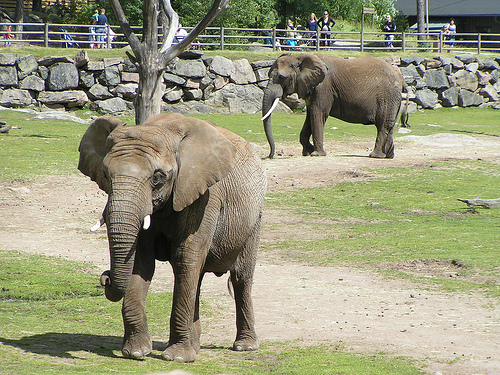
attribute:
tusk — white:
[259, 94, 281, 122]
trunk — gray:
[101, 224, 139, 302]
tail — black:
[402, 86, 413, 130]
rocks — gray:
[2, 47, 136, 118]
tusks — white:
[87, 216, 155, 235]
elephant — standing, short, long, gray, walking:
[79, 114, 267, 363]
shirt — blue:
[95, 13, 111, 27]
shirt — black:
[318, 17, 337, 29]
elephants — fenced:
[77, 51, 410, 363]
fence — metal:
[0, 21, 499, 56]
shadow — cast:
[2, 332, 170, 364]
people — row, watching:
[262, 9, 338, 51]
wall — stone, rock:
[0, 49, 499, 114]